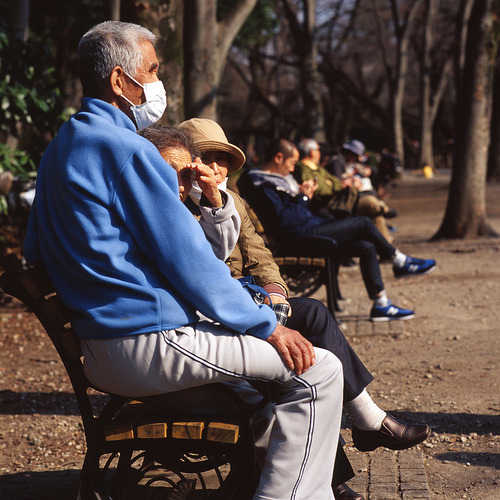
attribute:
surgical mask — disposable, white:
[106, 64, 168, 129]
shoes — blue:
[369, 250, 439, 323]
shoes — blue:
[367, 244, 447, 321]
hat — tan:
[176, 110, 247, 167]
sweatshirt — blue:
[38, 97, 280, 336]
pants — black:
[274, 288, 374, 404]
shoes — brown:
[338, 410, 432, 495]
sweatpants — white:
[78, 323, 348, 495]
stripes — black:
[155, 339, 315, 497]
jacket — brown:
[225, 191, 285, 296]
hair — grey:
[78, 17, 159, 101]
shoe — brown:
[341, 400, 429, 451]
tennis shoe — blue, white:
[393, 255, 442, 276]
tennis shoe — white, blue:
[367, 295, 416, 321]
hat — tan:
[175, 117, 246, 171]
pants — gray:
[82, 325, 348, 498]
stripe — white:
[157, 327, 236, 378]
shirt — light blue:
[32, 95, 272, 336]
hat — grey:
[345, 140, 363, 156]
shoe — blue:
[392, 252, 436, 280]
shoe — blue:
[368, 303, 418, 323]